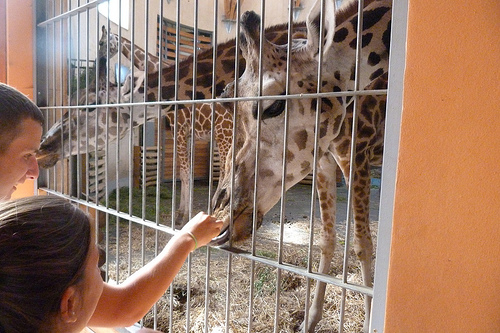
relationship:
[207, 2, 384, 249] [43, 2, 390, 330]
giraffe in enclosure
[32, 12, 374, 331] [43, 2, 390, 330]
giraffe in enclosure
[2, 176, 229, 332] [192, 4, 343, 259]
female petting giraffes head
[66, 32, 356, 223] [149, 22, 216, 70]
giraffes next gate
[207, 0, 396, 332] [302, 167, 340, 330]
giraffe has leg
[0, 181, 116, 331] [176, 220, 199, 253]
lady has band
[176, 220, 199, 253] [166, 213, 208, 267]
band on wrist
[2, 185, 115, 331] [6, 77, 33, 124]
girl has hair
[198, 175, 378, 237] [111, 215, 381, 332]
concrete beyond hay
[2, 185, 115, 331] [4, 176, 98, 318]
girl has hair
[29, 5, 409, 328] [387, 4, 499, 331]
cage has wall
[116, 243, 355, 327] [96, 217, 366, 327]
grass on ground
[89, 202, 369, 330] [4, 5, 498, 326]
grass in cage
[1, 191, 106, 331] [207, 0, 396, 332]
child looking giraffe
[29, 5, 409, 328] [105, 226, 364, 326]
cage has floor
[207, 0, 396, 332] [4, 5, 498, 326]
giraffe in cage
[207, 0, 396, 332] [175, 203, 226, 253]
giraffe has hand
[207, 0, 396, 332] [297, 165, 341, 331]
giraffe has leg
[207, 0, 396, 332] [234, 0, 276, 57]
giraffe has antler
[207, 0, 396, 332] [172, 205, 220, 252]
giraffe sniffs hand